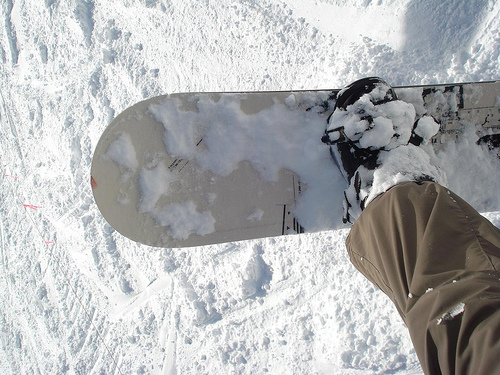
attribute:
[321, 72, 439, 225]
shoe — black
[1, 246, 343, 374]
snow — soft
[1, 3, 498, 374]
snow — white, tiny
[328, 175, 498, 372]
leg — khaki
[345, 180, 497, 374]
pant — khaki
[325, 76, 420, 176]
boot — black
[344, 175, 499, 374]
pant leg — brown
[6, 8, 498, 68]
snow — not smooth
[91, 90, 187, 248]
tip — round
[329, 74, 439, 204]
boot — black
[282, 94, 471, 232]
stripes — black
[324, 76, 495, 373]
person — snowboarding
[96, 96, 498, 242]
board — tan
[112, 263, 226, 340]
snow — whitey